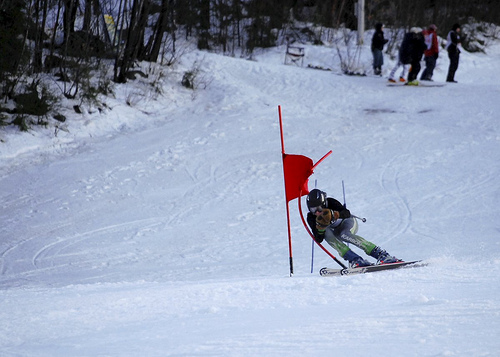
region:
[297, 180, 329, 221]
head of a person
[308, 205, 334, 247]
arm of a person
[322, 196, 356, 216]
arm of a person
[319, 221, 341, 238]
knee of a person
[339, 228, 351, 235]
knee of a person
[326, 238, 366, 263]
leg of a person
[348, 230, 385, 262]
leg of a person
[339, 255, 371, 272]
feet of a person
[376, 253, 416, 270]
feet of a person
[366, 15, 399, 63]
body of a person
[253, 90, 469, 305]
There is one person moving in the shot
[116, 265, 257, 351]
Snow on the ground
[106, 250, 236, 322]
The snow is white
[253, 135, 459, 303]
This person is skiing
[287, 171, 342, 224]
Has a helmet on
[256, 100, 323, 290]
This flag is red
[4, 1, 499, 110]
There are trees in the back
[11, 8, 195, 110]
The trees are bare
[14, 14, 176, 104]
Brown is the color of the trunks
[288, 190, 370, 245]
He has a black coat on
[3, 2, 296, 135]
these are the trees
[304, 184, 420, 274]
this is a man skiing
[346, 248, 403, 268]
these are his boots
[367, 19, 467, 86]
these are people standing in the snow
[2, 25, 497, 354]
this is the snow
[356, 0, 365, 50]
this is a telegram pole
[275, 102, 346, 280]
this is a red pole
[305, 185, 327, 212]
this is his helmet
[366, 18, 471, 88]
these are people skiing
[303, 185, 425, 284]
this is a man bending his knees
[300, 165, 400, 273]
this is a person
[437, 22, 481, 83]
this is a person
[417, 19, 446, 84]
this is a person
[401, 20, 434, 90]
this is a person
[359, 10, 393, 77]
this is a person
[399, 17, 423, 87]
this is a person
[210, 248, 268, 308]
this is snow on the ground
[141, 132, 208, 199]
this is snow on the ground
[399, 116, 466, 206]
this is snow on the ground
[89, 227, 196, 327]
the white snow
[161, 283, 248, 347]
the snow is white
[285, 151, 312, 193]
a red flag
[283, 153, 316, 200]
a red flag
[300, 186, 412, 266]
a person skiing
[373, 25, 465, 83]
people standing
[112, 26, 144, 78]
a tree branch that is brown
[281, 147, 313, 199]
the flag is red